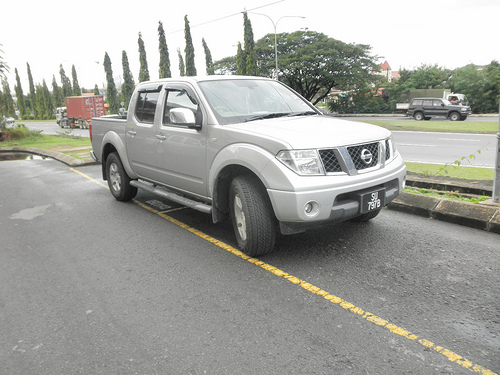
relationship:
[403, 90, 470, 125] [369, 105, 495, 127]
suv on top of sidewalk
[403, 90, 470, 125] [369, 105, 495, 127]
suv parked on sidewalk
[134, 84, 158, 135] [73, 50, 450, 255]
window on a truck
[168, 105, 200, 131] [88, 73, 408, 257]
side mirror on truck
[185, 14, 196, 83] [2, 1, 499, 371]
tree in city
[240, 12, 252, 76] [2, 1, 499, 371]
tree in city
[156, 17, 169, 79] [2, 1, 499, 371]
tree in city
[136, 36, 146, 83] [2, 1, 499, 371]
tree in city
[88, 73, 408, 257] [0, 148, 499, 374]
truck on road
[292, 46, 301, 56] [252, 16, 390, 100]
leaf on plant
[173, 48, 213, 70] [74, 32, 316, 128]
tree in city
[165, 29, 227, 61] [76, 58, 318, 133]
tree in city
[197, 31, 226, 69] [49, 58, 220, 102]
tree in city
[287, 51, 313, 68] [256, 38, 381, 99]
leaf on plant